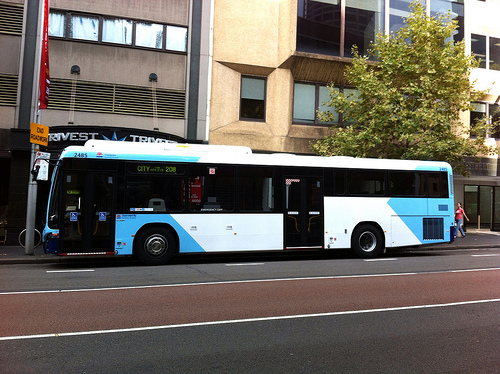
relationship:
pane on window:
[66, 10, 104, 44] [100, 13, 132, 47]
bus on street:
[28, 137, 456, 265] [1, 246, 496, 369]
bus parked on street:
[28, 137, 456, 265] [207, 266, 474, 339]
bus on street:
[28, 137, 456, 265] [63, 274, 457, 352]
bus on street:
[31, 139, 456, 263] [0, 264, 496, 370]